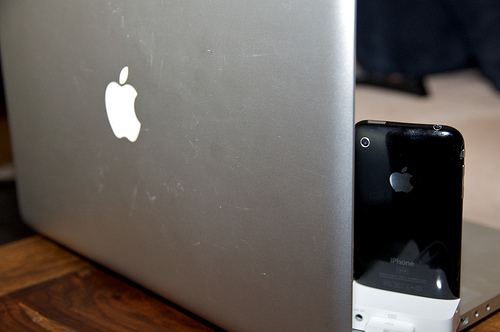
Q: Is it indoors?
A: Yes, it is indoors.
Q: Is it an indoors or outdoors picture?
A: It is indoors.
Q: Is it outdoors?
A: No, it is indoors.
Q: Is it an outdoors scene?
A: No, it is indoors.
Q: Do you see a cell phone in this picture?
A: Yes, there is a cell phone.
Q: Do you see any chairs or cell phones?
A: Yes, there is a cell phone.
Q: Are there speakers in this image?
A: No, there are no speakers.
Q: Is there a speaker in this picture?
A: No, there are no speakers.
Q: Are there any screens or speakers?
A: No, there are no speakers or screens.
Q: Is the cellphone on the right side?
A: Yes, the cellphone is on the right of the image.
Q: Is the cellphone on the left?
A: No, the cellphone is on the right of the image.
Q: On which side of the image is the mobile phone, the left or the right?
A: The mobile phone is on the right of the image.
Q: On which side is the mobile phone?
A: The mobile phone is on the right of the image.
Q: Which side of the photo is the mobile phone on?
A: The mobile phone is on the right of the image.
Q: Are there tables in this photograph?
A: Yes, there is a table.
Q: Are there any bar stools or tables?
A: Yes, there is a table.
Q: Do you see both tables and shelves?
A: No, there is a table but no shelves.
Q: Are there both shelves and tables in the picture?
A: No, there is a table but no shelves.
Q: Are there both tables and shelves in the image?
A: No, there is a table but no shelves.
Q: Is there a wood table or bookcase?
A: Yes, there is a wood table.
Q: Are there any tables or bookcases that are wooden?
A: Yes, the table is wooden.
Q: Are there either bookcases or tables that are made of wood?
A: Yes, the table is made of wood.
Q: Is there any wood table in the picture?
A: Yes, there is a wood table.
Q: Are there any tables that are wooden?
A: Yes, there is a table that is wooden.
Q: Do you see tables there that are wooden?
A: Yes, there is a table that is wooden.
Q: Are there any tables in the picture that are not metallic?
A: Yes, there is a wooden table.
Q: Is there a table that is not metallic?
A: Yes, there is a wooden table.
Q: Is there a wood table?
A: Yes, there is a table that is made of wood.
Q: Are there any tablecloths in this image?
A: No, there are no tablecloths.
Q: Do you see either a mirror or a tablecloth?
A: No, there are no tablecloths or mirrors.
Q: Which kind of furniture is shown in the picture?
A: The furniture is a table.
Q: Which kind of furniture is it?
A: The piece of furniture is a table.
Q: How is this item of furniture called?
A: This is a table.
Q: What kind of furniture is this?
A: This is a table.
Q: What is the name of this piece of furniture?
A: This is a table.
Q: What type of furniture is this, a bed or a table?
A: This is a table.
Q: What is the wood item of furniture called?
A: The piece of furniture is a table.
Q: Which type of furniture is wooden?
A: The furniture is a table.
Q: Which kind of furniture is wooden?
A: The furniture is a table.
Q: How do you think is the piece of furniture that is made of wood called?
A: The piece of furniture is a table.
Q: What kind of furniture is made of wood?
A: The furniture is a table.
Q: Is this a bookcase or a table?
A: This is a table.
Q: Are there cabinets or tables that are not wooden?
A: No, there is a table but it is wooden.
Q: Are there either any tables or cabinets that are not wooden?
A: No, there is a table but it is wooden.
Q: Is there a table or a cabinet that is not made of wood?
A: No, there is a table but it is made of wood.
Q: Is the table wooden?
A: Yes, the table is wooden.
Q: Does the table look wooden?
A: Yes, the table is wooden.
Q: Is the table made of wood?
A: Yes, the table is made of wood.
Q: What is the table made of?
A: The table is made of wood.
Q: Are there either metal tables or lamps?
A: No, there is a table but it is wooden.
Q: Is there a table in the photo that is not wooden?
A: No, there is a table but it is wooden.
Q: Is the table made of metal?
A: No, the table is made of wood.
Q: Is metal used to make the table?
A: No, the table is made of wood.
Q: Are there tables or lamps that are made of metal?
A: No, there is a table but it is made of wood.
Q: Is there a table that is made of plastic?
A: No, there is a table but it is made of wood.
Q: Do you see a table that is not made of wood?
A: No, there is a table but it is made of wood.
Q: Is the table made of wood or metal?
A: The table is made of wood.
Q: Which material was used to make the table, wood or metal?
A: The table is made of wood.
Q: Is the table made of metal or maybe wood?
A: The table is made of wood.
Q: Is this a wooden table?
A: Yes, this is a wooden table.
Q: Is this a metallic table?
A: No, this is a wooden table.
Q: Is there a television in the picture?
A: No, there are no televisions.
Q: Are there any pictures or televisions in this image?
A: No, there are no televisions or pictures.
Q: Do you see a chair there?
A: No, there are no chairs.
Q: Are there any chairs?
A: No, there are no chairs.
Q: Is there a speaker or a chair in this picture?
A: No, there are no chairs or speakers.